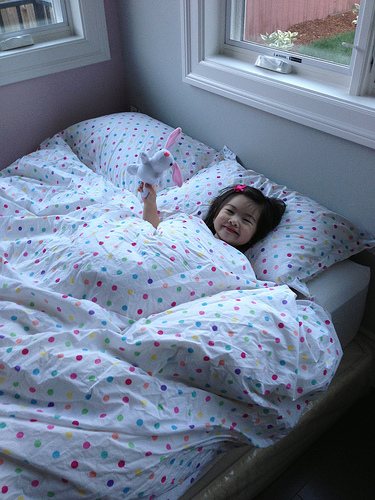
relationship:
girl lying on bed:
[138, 181, 286, 252] [2, 107, 374, 499]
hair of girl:
[223, 180, 299, 229] [138, 181, 286, 252]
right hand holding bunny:
[136, 181, 158, 204] [127, 126, 183, 199]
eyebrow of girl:
[228, 201, 237, 210] [138, 181, 286, 252]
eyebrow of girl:
[242, 208, 257, 221] [138, 181, 286, 252]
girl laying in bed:
[138, 181, 286, 252] [3, 147, 371, 494]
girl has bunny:
[138, 191, 290, 268] [127, 126, 183, 199]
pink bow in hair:
[233, 183, 246, 191] [204, 184, 286, 253]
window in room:
[174, 1, 374, 140] [16, 11, 325, 377]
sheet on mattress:
[316, 247, 373, 324] [183, 332, 375, 499]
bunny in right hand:
[127, 126, 182, 197] [136, 181, 158, 204]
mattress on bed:
[255, 366, 357, 465] [22, 98, 373, 405]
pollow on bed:
[152, 142, 373, 285] [13, 134, 276, 465]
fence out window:
[244, 2, 354, 41] [174, 1, 374, 140]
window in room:
[182, 1, 375, 154] [1, 5, 367, 309]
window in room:
[4, 2, 72, 47] [1, 5, 367, 309]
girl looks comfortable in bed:
[138, 181, 286, 252] [51, 161, 256, 413]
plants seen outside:
[259, 3, 360, 50] [243, 10, 362, 63]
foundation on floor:
[227, 375, 373, 497] [196, 448, 371, 495]